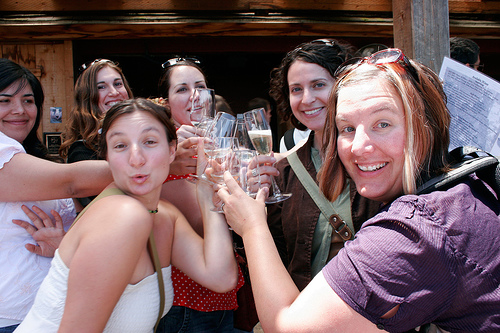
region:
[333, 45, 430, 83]
Red, girls, eye glasses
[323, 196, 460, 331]
A purple sleeve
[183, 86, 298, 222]
Glasses toasting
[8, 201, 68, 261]
A white woman's hand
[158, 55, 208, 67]
A pair of black sunglasses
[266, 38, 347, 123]
Black curly hair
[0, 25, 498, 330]
Friends toasting to something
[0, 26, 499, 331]
A group of friends posing for a picture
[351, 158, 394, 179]
A woman's smile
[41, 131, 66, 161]
A plaque on a wall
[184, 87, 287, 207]
Champagne glasses being toasted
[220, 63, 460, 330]
Women with sunglasses on her head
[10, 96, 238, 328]
Woman making kiss lips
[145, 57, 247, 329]
Woman wearing red and white polka dot shirt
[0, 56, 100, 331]
Brunette female waving her hand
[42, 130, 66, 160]
Sign on the wall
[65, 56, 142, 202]
Woman smiling wearing black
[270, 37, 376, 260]
Woman with curly brown hair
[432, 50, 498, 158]
Restaurant menu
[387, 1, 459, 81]
Wood support beam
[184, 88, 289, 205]
a collection of glasses held by women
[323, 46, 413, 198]
a woman with sunglasses on her head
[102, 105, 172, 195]
a woman making a kissing face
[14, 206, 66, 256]
the hand of a woman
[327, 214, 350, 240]
buckle on a purse strap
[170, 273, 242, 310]
red and white polka dots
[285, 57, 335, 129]
the face of a woman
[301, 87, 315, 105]
nose of a woman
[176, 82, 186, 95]
right eye of a woman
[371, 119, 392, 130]
a woman's eye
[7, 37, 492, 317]
Group of people holding glasses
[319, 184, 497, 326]
A purple shirt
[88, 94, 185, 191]
Woman has brown hair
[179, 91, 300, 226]
Many champagne glasses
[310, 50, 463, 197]
Person has blonde hair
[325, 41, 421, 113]
Eyeglasses on top of person's head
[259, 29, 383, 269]
Woman wearing a brown jacket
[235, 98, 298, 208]
Champagne in a glass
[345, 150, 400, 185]
A person's teeth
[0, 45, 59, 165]
Woman has black hair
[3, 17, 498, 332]
Women at a party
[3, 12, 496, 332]
Women holding up glasses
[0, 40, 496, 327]
Six women holding up glasses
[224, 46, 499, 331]
Two women smiling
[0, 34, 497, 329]
Six women smiling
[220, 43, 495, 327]
Woman wearing purple top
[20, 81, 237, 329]
Woman wearing white top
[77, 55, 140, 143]
Woman with blonde hair smiling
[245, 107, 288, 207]
Glass of champagne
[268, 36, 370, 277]
Woman with dark hair smiling